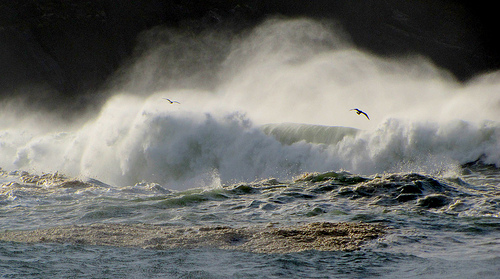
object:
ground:
[358, 207, 401, 238]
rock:
[3, 4, 492, 114]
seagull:
[161, 95, 181, 109]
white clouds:
[376, 13, 421, 46]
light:
[0, 172, 500, 277]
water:
[1, 18, 498, 276]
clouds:
[0, 16, 500, 163]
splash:
[9, 30, 496, 175]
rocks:
[18, 216, 381, 254]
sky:
[0, 0, 499, 104]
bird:
[347, 101, 374, 123]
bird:
[161, 90, 188, 107]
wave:
[0, 93, 499, 193]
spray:
[1, 7, 495, 195]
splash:
[90, 79, 467, 208]